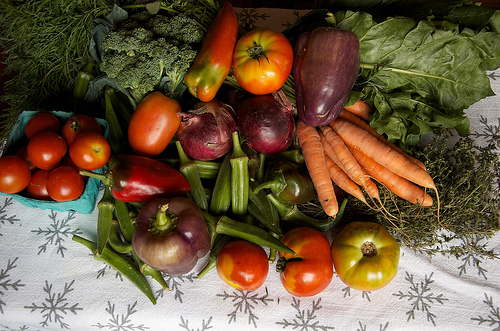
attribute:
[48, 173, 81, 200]
tomatoe — ripe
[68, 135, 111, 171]
tomatoe — ripe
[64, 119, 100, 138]
tomatoe — ripe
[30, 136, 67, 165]
tomatoe — ripe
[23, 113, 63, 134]
tomatoe — ripe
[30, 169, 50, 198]
tomatoe — ripe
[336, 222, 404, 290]
tomatoe — green, unripe, round, shiny, plump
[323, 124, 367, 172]
carrot — small, orange, fresh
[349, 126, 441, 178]
carrot — small, orange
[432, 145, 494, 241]
rosemary — green, fresh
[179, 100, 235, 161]
onion — maroon, red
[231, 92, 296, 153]
onion — maroon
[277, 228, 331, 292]
tomatoe — red, ripe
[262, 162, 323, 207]
pepper — green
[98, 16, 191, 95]
broccoli — green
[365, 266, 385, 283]
light — shining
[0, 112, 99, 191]
tomatoes — orange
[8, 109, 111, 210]
carton — green, cardboard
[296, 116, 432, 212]
carrots — fresh, freshly grown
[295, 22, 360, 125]
pepper — purple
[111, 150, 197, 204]
pepper — large, reddish, purple, red, long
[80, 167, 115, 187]
end — green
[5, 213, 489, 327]
tablecloth — white, snowflake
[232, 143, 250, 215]
okra — ridged, green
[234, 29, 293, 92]
tomatoe — red, yellow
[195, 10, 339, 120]
stalk — grassy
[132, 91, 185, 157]
tomatoe — red, ripe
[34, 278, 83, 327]
snowflake — gray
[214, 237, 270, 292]
tomatoe — small, red, ripe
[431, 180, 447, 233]
root — orange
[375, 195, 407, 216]
root — orange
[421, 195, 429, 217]
root — orange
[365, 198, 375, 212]
root — orange